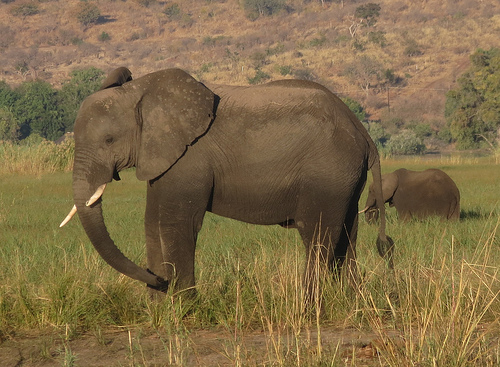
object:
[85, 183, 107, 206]
tusk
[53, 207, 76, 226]
tusk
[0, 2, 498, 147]
hillside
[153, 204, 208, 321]
front leg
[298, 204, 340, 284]
back leg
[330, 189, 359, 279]
back leg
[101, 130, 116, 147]
eye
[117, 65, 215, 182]
ear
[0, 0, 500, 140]
desert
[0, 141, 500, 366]
grass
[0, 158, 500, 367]
ground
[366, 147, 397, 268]
elephant tail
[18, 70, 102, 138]
trees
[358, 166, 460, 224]
elephant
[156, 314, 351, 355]
dirt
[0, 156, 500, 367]
field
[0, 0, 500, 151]
hill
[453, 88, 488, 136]
shrubs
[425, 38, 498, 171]
tree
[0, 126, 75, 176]
bush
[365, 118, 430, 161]
bush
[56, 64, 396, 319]
elephant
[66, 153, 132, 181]
jaws